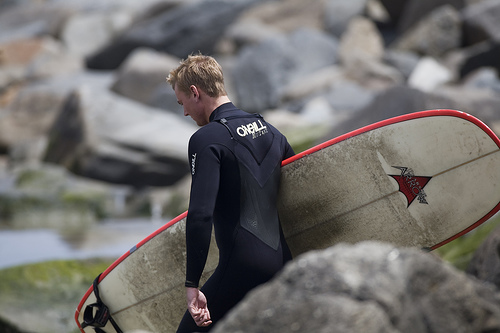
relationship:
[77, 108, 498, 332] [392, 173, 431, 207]
surfboard has arrow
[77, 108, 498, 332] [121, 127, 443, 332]
surfboard has dirt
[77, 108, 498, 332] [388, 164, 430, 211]
surfboard has logo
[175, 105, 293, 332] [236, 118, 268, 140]
swimsuit has logo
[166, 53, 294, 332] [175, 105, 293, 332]
surfer wearing swimsuit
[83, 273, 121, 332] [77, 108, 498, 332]
strap around surfboard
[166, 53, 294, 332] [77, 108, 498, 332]
surfer carrying surfboard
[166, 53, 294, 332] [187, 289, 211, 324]
surfer has left hand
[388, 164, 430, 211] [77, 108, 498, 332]
logo on top of surfboard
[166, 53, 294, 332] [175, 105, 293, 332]
surfer has swimsuit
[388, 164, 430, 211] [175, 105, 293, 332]
logo on back of swimsuit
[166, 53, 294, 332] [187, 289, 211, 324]
surfer hs left hand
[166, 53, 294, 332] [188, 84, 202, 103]
surfer has ear